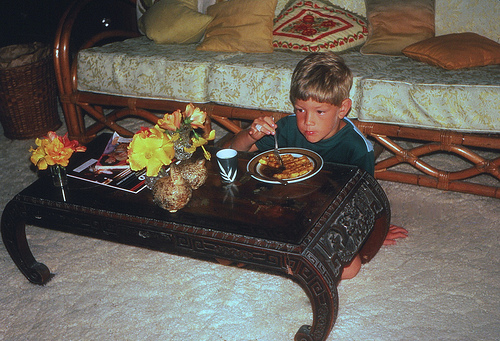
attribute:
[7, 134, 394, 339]
table — wood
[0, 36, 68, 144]
basket — tall and wicker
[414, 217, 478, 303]
carpet — white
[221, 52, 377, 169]
boy — little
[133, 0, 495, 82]
pillows — yellow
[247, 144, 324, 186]
plate — with food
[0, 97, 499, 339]
carpet — white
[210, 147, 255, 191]
cup — black and white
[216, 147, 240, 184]
cup — white, black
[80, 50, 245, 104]
couch — white, yellow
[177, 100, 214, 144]
flower — yellow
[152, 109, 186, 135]
flower — yellow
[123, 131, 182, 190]
flower — yellow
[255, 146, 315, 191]
waffles — brown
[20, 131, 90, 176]
flower — orange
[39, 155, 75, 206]
vase — black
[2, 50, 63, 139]
basket — tall and woven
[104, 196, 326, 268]
coffee table — brown